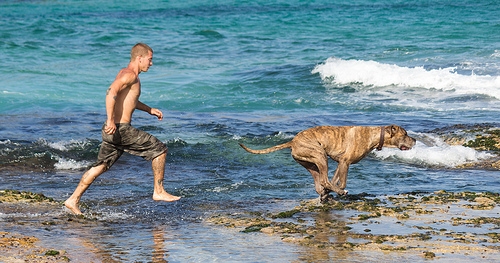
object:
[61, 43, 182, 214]
man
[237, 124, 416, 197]
dog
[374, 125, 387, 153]
collar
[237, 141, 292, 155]
tail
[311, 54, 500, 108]
wave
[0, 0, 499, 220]
ocean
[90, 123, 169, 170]
shorts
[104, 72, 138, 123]
arm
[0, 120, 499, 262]
shore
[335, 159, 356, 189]
legs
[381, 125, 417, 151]
head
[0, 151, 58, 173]
rocks